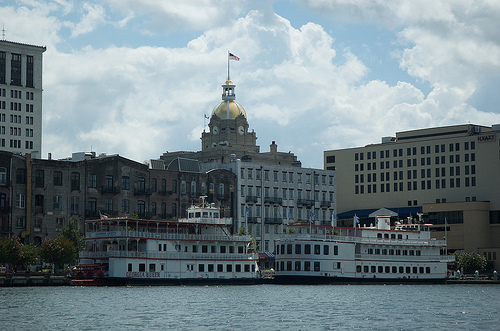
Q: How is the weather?
A: It is cloudy.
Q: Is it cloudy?
A: Yes, it is cloudy.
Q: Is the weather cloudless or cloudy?
A: It is cloudy.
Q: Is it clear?
A: No, it is cloudy.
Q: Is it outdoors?
A: Yes, it is outdoors.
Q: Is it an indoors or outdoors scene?
A: It is outdoors.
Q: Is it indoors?
A: No, it is outdoors.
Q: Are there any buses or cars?
A: No, there are no cars or buses.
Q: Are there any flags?
A: Yes, there is a flag.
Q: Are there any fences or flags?
A: Yes, there is a flag.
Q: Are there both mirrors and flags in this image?
A: No, there is a flag but no mirrors.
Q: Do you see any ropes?
A: No, there are no ropes.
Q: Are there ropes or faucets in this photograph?
A: No, there are no ropes or faucets.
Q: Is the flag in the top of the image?
A: Yes, the flag is in the top of the image.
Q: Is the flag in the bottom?
A: No, the flag is in the top of the image.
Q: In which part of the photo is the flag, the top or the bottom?
A: The flag is in the top of the image.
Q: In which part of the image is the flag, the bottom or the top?
A: The flag is in the top of the image.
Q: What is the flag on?
A: The flag is on the building.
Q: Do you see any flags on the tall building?
A: Yes, there is a flag on the building.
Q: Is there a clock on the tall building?
A: No, there is a flag on the building.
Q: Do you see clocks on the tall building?
A: No, there is a flag on the building.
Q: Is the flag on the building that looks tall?
A: Yes, the flag is on the building.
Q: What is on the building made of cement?
A: The flag is on the building.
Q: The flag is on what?
A: The flag is on the building.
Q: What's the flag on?
A: The flag is on the building.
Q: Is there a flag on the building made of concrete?
A: Yes, there is a flag on the building.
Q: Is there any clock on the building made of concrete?
A: No, there is a flag on the building.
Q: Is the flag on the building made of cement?
A: Yes, the flag is on the building.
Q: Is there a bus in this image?
A: No, there are no buses.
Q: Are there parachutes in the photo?
A: No, there are no parachutes.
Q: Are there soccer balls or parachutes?
A: No, there are no parachutes or soccer balls.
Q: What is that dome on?
A: The dome is on the building.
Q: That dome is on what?
A: The dome is on the building.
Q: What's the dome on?
A: The dome is on the building.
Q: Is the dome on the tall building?
A: Yes, the dome is on the building.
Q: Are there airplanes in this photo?
A: No, there are no airplanes.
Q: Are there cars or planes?
A: No, there are no planes or cars.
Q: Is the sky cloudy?
A: Yes, the sky is cloudy.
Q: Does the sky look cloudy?
A: Yes, the sky is cloudy.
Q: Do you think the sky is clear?
A: No, the sky is cloudy.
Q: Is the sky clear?
A: No, the sky is cloudy.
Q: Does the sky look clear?
A: No, the sky is cloudy.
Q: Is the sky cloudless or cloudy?
A: The sky is cloudy.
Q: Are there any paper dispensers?
A: No, there are no paper dispensers.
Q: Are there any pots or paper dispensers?
A: No, there are no paper dispensers or pots.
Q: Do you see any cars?
A: No, there are no cars.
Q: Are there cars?
A: No, there are no cars.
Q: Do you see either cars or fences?
A: No, there are no cars or fences.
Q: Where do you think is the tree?
A: The tree is on the shore.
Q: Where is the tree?
A: The tree is on the shore.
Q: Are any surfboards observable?
A: No, there are no surfboards.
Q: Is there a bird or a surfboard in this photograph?
A: No, there are no surfboards or birds.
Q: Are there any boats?
A: Yes, there is a boat.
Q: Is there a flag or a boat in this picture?
A: Yes, there is a boat.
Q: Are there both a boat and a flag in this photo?
A: Yes, there are both a boat and a flag.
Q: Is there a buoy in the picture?
A: No, there are no buoys.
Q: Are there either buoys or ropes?
A: No, there are no buoys or ropes.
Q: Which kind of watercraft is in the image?
A: The watercraft is a boat.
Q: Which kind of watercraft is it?
A: The watercraft is a boat.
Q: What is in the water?
A: The boat is in the water.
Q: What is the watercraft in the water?
A: The watercraft is a boat.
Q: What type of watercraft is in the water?
A: The watercraft is a boat.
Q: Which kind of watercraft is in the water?
A: The watercraft is a boat.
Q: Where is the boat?
A: The boat is in the water.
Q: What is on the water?
A: The boat is on the water.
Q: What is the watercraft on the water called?
A: The watercraft is a boat.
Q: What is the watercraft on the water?
A: The watercraft is a boat.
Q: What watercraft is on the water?
A: The watercraft is a boat.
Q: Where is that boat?
A: The boat is on the water.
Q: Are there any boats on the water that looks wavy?
A: Yes, there is a boat on the water.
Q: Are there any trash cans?
A: No, there are no trash cans.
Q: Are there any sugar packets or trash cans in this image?
A: No, there are no trash cans or sugar packets.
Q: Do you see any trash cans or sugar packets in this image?
A: No, there are no trash cans or sugar packets.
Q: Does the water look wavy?
A: Yes, the water is wavy.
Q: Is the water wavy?
A: Yes, the water is wavy.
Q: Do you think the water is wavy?
A: Yes, the water is wavy.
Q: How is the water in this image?
A: The water is wavy.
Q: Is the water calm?
A: No, the water is wavy.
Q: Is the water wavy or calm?
A: The water is wavy.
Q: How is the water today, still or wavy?
A: The water is wavy.